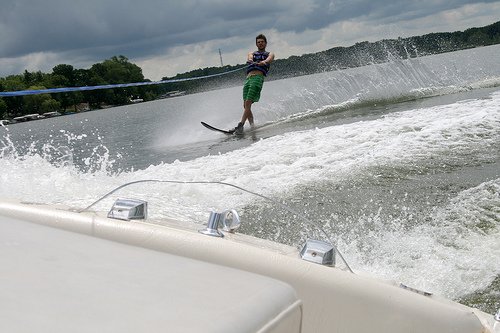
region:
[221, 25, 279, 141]
Water skier holds a rope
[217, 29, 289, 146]
Water skier holds rope with both hands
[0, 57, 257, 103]
Rope is blue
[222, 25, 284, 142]
Water skier wears green shorts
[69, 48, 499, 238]
Water is choppy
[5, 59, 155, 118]
Trees are green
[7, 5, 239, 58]
Sky is cloudy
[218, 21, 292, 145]
Boy wears a tank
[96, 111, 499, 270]
Choppy water formed by the passage of boat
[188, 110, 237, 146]
Ski is up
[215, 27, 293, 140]
Surfer holding a rope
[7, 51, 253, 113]
Rope is long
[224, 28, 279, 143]
Surfer wears green shorts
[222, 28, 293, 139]
Man wears a tank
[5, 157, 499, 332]
Boat is white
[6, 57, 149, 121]
Green trees near body of water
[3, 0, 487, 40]
Sky has black clouds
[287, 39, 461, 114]
Splashes formed by the passage of surfer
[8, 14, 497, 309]
water sports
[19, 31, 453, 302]
a man is waterskiing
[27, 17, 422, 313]
a boat pulls a man on waterskis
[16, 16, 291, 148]
the man holds a blue rope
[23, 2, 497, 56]
it is a cloudy day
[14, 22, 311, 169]
the man is standing on skis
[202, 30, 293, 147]
the water skier is wearing green shorts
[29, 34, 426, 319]
a man is pulled behind the boat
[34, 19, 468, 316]
the man is watersking behind a boat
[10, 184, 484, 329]
the boat is white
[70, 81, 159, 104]
The cable is blue.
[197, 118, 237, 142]
The person is on water skis.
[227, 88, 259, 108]
The shorts are green.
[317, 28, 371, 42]
Clouds in the sky.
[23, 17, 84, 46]
The sky is grey.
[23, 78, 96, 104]
The trees are green.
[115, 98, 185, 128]
The water is grey.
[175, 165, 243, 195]
The water is white.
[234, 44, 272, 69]
The life vest is blue.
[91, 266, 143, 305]
The boat is white.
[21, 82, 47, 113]
a green tree in a distance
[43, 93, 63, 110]
a green tree in a distance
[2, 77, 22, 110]
a green tree in a distance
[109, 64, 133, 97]
a green tree in a distance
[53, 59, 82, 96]
a green tree in a distance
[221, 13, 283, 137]
a man surfing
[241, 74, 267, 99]
a pair of green shorts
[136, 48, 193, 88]
a cloud in the sky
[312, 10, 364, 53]
a cloud in the sky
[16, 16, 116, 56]
a cloud in the sky